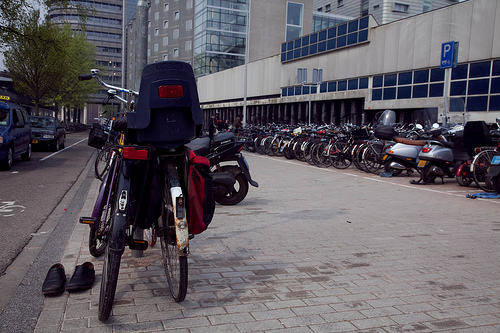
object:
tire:
[88, 223, 108, 258]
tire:
[209, 165, 248, 205]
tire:
[469, 150, 500, 192]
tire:
[93, 147, 115, 182]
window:
[448, 63, 468, 80]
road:
[0, 167, 78, 331]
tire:
[98, 223, 123, 323]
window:
[372, 75, 383, 87]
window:
[412, 70, 428, 85]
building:
[49, 0, 500, 131]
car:
[28, 115, 66, 151]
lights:
[296, 69, 307, 83]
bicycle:
[81, 69, 148, 321]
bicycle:
[143, 142, 195, 302]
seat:
[125, 61, 205, 148]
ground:
[0, 142, 499, 333]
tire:
[160, 221, 189, 302]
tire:
[88, 174, 109, 258]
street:
[0, 166, 90, 332]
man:
[207, 115, 229, 142]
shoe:
[41, 263, 65, 296]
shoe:
[65, 261, 96, 291]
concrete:
[265, 180, 386, 238]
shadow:
[119, 237, 288, 330]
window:
[398, 86, 412, 98]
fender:
[107, 168, 131, 252]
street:
[236, 199, 473, 333]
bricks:
[220, 234, 497, 330]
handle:
[88, 69, 141, 94]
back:
[79, 61, 259, 322]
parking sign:
[440, 41, 457, 68]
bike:
[409, 117, 500, 185]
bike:
[373, 125, 419, 176]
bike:
[360, 130, 383, 174]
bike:
[325, 127, 361, 170]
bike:
[311, 133, 338, 168]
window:
[398, 71, 412, 85]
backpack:
[127, 60, 202, 149]